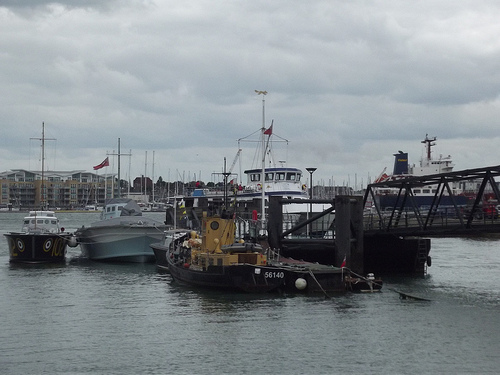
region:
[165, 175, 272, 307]
yellow tug boat docked in water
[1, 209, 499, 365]
calm water with boats docked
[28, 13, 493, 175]
overcast very cloudy sky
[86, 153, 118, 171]
red flag flying on white ship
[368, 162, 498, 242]
black metal lattice style walkway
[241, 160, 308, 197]
white observation tower on dock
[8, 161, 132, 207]
large white building in background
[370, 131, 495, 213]
very large cruise size ship with blue chimney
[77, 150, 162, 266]
white sail boat with red flag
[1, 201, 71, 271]
black boat with white top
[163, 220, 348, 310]
A large brown and yellow tug boat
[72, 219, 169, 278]
Light blue and white boat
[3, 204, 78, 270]
A brown and white boat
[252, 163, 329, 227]
A large white boat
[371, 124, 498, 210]
A large white and blue boat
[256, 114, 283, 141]
A flag on white boat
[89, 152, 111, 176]
A flag flying on boat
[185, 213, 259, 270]
Yellow top of tug boat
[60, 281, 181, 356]
Water with small ripples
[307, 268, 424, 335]
Ropes in water behind tug boat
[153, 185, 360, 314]
this is a ship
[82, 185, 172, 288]
this is a ship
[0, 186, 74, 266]
this is a ship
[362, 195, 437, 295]
this is a ship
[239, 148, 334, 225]
this is a ship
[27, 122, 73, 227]
this is a pole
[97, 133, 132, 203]
this is a pole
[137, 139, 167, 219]
this is a pole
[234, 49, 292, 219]
this is a pole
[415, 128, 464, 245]
this is a pole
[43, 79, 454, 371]
the scene is in a port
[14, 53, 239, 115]
the sky is cloudy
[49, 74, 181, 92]
the sky is dark in colour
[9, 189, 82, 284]
the boat is black in colour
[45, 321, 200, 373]
the water is calm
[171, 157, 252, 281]
the boat has a yellow mast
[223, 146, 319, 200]
the baoat is white in color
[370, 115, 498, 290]
the bridge is mettallick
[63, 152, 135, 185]
the sail is cast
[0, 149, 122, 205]
the house is brown in colour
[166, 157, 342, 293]
small tug boat at dock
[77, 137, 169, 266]
gray aluminum boat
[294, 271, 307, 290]
dock boat bumper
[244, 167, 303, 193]
bridge of fishing vessel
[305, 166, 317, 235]
exterior light fixture on dock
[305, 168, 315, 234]
light fixture on metal pole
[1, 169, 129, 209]
modern buildings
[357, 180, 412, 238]
metal gangplank to docks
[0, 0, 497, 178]
dark cloudy sky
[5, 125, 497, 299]
marina with vessels of many types